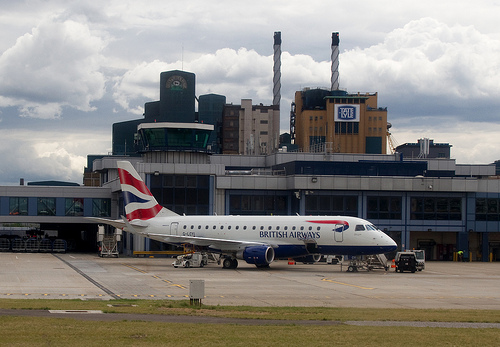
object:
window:
[15, 197, 28, 216]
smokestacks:
[272, 30, 281, 105]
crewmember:
[456, 250, 464, 261]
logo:
[159, 72, 188, 120]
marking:
[186, 278, 208, 306]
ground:
[0, 247, 499, 346]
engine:
[227, 246, 275, 265]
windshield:
[355, 222, 381, 234]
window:
[374, 197, 388, 213]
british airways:
[0, 246, 499, 346]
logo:
[255, 227, 321, 239]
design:
[118, 167, 163, 222]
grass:
[0, 297, 499, 346]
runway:
[0, 248, 499, 308]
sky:
[0, 0, 499, 185]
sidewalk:
[0, 310, 499, 328]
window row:
[181, 220, 321, 232]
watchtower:
[132, 117, 215, 153]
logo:
[333, 104, 361, 121]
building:
[240, 97, 280, 154]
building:
[218, 102, 238, 156]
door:
[332, 222, 342, 244]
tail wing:
[118, 161, 179, 219]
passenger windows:
[315, 225, 321, 231]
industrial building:
[291, 88, 389, 154]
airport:
[0, 31, 499, 347]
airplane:
[81, 159, 398, 274]